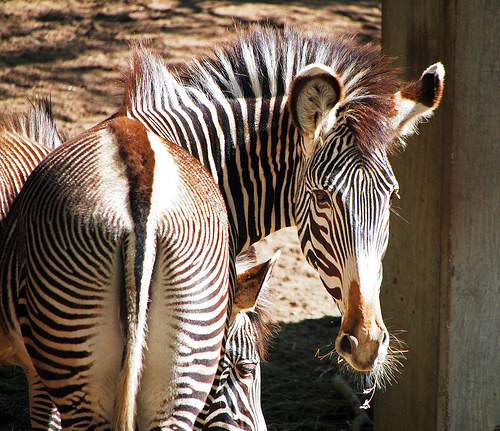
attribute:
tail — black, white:
[114, 221, 161, 429]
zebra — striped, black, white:
[21, 22, 465, 429]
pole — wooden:
[429, 189, 485, 428]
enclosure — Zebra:
[393, 183, 470, 316]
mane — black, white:
[178, 25, 401, 106]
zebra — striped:
[9, 50, 455, 430]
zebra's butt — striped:
[39, 207, 122, 381]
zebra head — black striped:
[286, 44, 484, 422]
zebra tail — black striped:
[115, 224, 162, 429]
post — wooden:
[368, 6, 498, 429]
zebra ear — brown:
[235, 248, 284, 311]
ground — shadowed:
[8, 3, 393, 428]